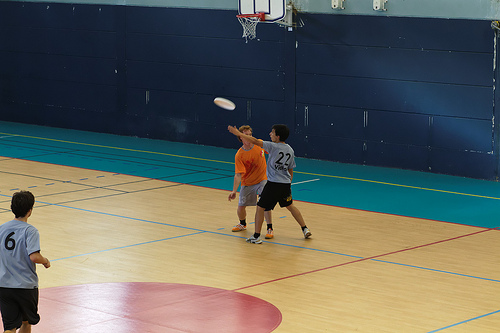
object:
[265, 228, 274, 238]
orange sneaker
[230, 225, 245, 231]
orange sneaker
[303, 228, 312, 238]
shoe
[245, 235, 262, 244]
shoe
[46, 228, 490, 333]
line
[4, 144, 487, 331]
floor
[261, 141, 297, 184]
shirt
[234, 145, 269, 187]
shirt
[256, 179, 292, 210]
black shorts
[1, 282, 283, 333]
circle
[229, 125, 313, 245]
boy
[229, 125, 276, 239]
boy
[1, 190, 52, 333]
boy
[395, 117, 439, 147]
ground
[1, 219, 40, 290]
shirt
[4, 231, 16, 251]
6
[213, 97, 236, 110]
frisbee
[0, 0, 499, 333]
court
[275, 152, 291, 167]
number 22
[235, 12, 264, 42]
basketball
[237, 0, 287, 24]
backboard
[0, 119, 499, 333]
flat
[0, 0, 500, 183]
wall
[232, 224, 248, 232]
feet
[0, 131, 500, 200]
yellow line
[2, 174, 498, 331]
blue lines